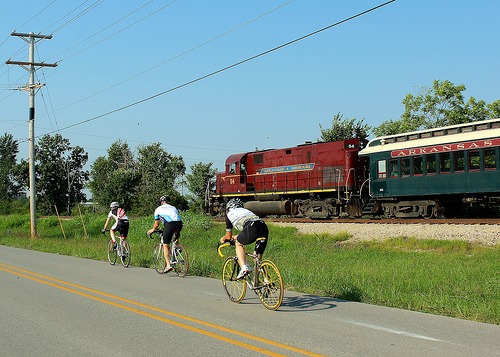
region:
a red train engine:
[194, 130, 364, 215]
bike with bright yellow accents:
[214, 232, 290, 321]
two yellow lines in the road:
[16, 253, 201, 348]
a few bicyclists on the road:
[56, 189, 315, 336]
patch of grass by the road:
[287, 226, 471, 339]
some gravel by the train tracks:
[352, 207, 484, 252]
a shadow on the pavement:
[266, 282, 361, 324]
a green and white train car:
[358, 114, 498, 205]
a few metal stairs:
[360, 193, 385, 218]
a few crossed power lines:
[4, 87, 86, 157]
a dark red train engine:
[210, 141, 356, 221]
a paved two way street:
[0, 239, 498, 353]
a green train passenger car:
[360, 121, 499, 221]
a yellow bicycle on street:
[214, 232, 288, 311]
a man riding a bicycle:
[210, 196, 285, 306]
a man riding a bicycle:
[146, 189, 196, 278]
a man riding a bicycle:
[98, 199, 135, 269]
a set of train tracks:
[208, 214, 495, 229]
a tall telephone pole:
[4, 20, 62, 240]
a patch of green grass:
[2, 206, 499, 326]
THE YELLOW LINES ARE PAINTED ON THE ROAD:
[0, 257, 330, 355]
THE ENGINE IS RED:
[204, 133, 369, 232]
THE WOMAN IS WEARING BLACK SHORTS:
[218, 194, 276, 295]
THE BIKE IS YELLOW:
[211, 237, 286, 315]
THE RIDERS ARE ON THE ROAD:
[94, 187, 286, 313]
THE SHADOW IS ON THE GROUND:
[240, 272, 363, 324]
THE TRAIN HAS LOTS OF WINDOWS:
[375, 141, 499, 182]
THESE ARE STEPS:
[355, 193, 385, 225]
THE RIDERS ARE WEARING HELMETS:
[96, 195, 273, 310]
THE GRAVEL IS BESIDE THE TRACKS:
[203, 217, 498, 251]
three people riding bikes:
[68, 172, 323, 294]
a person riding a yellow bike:
[222, 182, 294, 310]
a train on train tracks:
[199, 105, 490, 216]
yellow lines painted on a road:
[93, 274, 222, 349]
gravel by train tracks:
[338, 219, 471, 238]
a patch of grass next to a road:
[376, 227, 470, 346]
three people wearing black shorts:
[78, 196, 289, 263]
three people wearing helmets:
[96, 182, 263, 234]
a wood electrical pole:
[19, 60, 51, 254]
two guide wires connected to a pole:
[61, 64, 96, 240]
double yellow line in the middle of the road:
[23, 278, 214, 355]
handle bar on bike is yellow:
[215, 235, 228, 263]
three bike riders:
[102, 191, 299, 297]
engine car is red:
[226, 151, 336, 202]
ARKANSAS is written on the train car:
[397, 137, 489, 159]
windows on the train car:
[393, 155, 499, 173]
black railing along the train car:
[234, 163, 348, 197]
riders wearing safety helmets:
[101, 193, 244, 214]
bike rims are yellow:
[221, 256, 301, 318]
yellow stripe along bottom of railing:
[221, 177, 354, 200]